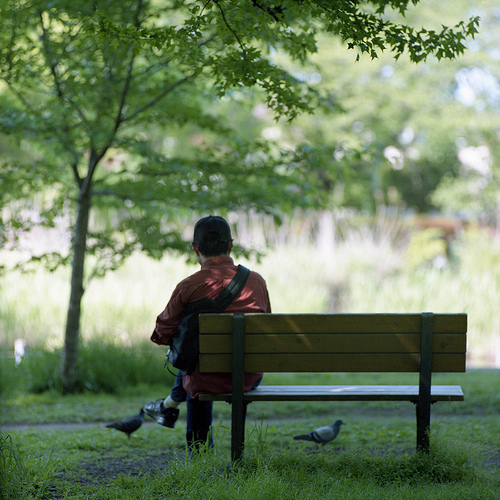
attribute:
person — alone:
[140, 213, 270, 461]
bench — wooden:
[195, 306, 465, 470]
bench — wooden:
[194, 309, 467, 458]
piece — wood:
[198, 311, 469, 335]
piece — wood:
[198, 334, 464, 354]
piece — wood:
[198, 354, 464, 374]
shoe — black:
[141, 399, 181, 429]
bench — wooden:
[189, 311, 468, 423]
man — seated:
[103, 185, 344, 466]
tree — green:
[3, 39, 310, 366]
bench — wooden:
[169, 265, 485, 423]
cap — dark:
[162, 211, 262, 268]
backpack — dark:
[154, 311, 284, 421]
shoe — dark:
[87, 344, 254, 478]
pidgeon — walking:
[103, 402, 165, 452]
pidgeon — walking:
[298, 423, 381, 482]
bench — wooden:
[194, 314, 496, 431]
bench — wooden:
[184, 311, 485, 406]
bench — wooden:
[221, 263, 464, 471]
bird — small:
[296, 414, 381, 493]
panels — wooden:
[181, 309, 496, 366]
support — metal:
[217, 323, 267, 471]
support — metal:
[385, 304, 477, 490]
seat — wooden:
[159, 297, 492, 410]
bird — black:
[96, 385, 181, 493]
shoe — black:
[111, 349, 199, 496]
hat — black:
[166, 222, 266, 282]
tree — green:
[18, 28, 298, 307]